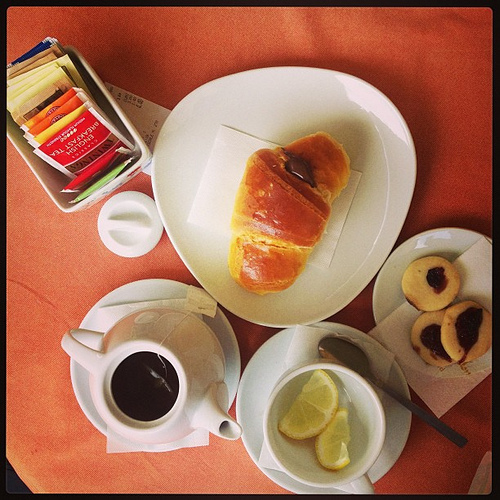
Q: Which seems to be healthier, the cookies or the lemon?
A: The lemon is healthier than the cookies.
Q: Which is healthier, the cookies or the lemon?
A: The lemon is healthier than the cookies.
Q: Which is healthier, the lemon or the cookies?
A: The lemon is healthier than the cookies.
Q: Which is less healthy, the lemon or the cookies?
A: The cookies is less healthy than the lemon.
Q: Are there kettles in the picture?
A: Yes, there is a kettle.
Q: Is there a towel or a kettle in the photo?
A: Yes, there is a kettle.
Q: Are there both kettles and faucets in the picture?
A: No, there is a kettle but no faucets.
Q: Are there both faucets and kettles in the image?
A: No, there is a kettle but no faucets.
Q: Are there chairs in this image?
A: No, there are no chairs.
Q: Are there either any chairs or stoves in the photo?
A: No, there are no chairs or stoves.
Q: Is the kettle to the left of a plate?
A: Yes, the kettle is to the left of a plate.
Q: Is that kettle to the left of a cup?
A: No, the kettle is to the left of a plate.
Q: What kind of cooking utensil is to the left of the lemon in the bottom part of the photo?
A: The cooking utensil is a kettle.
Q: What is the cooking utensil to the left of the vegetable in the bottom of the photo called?
A: The cooking utensil is a kettle.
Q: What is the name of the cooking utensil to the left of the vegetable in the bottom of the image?
A: The cooking utensil is a kettle.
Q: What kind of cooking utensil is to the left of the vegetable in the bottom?
A: The cooking utensil is a kettle.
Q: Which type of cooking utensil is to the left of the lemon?
A: The cooking utensil is a kettle.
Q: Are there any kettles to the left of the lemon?
A: Yes, there is a kettle to the left of the lemon.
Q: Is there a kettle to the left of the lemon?
A: Yes, there is a kettle to the left of the lemon.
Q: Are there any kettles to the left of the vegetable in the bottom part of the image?
A: Yes, there is a kettle to the left of the lemon.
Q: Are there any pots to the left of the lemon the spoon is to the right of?
A: No, there is a kettle to the left of the lemon.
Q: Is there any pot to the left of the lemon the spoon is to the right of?
A: No, there is a kettle to the left of the lemon.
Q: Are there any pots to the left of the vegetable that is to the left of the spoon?
A: No, there is a kettle to the left of the lemon.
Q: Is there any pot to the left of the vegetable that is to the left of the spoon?
A: No, there is a kettle to the left of the lemon.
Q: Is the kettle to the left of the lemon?
A: Yes, the kettle is to the left of the lemon.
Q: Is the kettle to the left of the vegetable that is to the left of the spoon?
A: Yes, the kettle is to the left of the lemon.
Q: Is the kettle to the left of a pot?
A: No, the kettle is to the left of the lemon.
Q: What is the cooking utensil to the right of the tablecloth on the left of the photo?
A: The cooking utensil is a kettle.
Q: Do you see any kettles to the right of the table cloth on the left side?
A: Yes, there is a kettle to the right of the tablecloth.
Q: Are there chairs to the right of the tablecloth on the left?
A: No, there is a kettle to the right of the table cloth.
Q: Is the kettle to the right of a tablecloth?
A: Yes, the kettle is to the right of a tablecloth.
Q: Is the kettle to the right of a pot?
A: No, the kettle is to the right of a tablecloth.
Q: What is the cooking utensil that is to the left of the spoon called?
A: The cooking utensil is a kettle.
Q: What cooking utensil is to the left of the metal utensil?
A: The cooking utensil is a kettle.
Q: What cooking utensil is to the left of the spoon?
A: The cooking utensil is a kettle.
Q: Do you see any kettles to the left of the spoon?
A: Yes, there is a kettle to the left of the spoon.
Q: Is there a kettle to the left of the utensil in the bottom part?
A: Yes, there is a kettle to the left of the spoon.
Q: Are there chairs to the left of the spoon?
A: No, there is a kettle to the left of the spoon.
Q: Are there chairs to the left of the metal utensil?
A: No, there is a kettle to the left of the spoon.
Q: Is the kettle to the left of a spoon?
A: Yes, the kettle is to the left of a spoon.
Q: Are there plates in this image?
A: Yes, there is a plate.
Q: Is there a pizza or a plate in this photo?
A: Yes, there is a plate.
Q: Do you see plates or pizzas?
A: Yes, there is a plate.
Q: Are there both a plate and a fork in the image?
A: No, there is a plate but no forks.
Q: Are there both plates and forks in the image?
A: No, there is a plate but no forks.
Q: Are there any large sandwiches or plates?
A: Yes, there is a large plate.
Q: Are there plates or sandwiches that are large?
A: Yes, the plate is large.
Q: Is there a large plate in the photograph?
A: Yes, there is a large plate.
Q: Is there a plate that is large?
A: Yes, there is a plate that is large.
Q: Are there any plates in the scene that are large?
A: Yes, there is a plate that is large.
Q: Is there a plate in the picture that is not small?
A: Yes, there is a large plate.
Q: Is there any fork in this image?
A: No, there are no forks.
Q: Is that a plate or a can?
A: That is a plate.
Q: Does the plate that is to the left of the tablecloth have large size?
A: Yes, the plate is large.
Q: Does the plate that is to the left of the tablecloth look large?
A: Yes, the plate is large.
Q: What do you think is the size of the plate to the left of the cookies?
A: The plate is large.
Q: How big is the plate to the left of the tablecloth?
A: The plate is large.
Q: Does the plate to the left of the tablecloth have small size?
A: No, the plate is large.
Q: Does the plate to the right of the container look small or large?
A: The plate is large.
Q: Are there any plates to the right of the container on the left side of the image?
A: Yes, there is a plate to the right of the container.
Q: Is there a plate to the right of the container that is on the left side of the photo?
A: Yes, there is a plate to the right of the container.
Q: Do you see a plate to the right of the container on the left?
A: Yes, there is a plate to the right of the container.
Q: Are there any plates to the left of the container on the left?
A: No, the plate is to the right of the container.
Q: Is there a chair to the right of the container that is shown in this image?
A: No, there is a plate to the right of the container.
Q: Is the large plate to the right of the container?
A: Yes, the plate is to the right of the container.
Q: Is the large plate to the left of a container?
A: No, the plate is to the right of a container.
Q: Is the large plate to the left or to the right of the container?
A: The plate is to the right of the container.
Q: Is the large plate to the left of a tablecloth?
A: Yes, the plate is to the left of a tablecloth.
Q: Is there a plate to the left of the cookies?
A: Yes, there is a plate to the left of the cookies.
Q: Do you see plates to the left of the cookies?
A: Yes, there is a plate to the left of the cookies.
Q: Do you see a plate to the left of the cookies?
A: Yes, there is a plate to the left of the cookies.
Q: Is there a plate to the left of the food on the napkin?
A: Yes, there is a plate to the left of the cookies.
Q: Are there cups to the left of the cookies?
A: No, there is a plate to the left of the cookies.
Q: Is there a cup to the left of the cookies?
A: No, there is a plate to the left of the cookies.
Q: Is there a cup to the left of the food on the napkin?
A: No, there is a plate to the left of the cookies.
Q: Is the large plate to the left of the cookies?
A: Yes, the plate is to the left of the cookies.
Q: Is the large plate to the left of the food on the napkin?
A: Yes, the plate is to the left of the cookies.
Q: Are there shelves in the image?
A: No, there are no shelves.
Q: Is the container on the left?
A: Yes, the container is on the left of the image.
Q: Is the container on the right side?
A: No, the container is on the left of the image.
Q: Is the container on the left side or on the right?
A: The container is on the left of the image.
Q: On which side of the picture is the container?
A: The container is on the left of the image.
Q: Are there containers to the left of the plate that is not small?
A: Yes, there is a container to the left of the plate.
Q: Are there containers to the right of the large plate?
A: No, the container is to the left of the plate.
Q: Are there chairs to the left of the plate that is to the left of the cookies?
A: No, there is a container to the left of the plate.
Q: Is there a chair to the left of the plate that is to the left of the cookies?
A: No, there is a container to the left of the plate.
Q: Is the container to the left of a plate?
A: Yes, the container is to the left of a plate.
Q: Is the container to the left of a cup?
A: No, the container is to the left of a plate.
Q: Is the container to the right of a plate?
A: No, the container is to the left of a plate.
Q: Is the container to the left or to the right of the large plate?
A: The container is to the left of the plate.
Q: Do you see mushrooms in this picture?
A: No, there are no mushrooms.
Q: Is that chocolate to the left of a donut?
A: No, the chocolate is to the left of the tablecloth.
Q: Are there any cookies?
A: Yes, there are cookies.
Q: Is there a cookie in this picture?
A: Yes, there are cookies.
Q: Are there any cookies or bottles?
A: Yes, there are cookies.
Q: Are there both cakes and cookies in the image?
A: No, there are cookies but no cakes.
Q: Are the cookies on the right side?
A: Yes, the cookies are on the right of the image.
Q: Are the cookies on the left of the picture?
A: No, the cookies are on the right of the image.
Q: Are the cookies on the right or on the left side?
A: The cookies are on the right of the image.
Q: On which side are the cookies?
A: The cookies are on the right of the image.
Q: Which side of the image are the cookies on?
A: The cookies are on the right of the image.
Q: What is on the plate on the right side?
A: The cookies are on the plate.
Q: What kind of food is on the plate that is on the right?
A: The food is cookies.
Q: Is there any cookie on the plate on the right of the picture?
A: Yes, there are cookies on the plate.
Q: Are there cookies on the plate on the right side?
A: Yes, there are cookies on the plate.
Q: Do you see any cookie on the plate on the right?
A: Yes, there are cookies on the plate.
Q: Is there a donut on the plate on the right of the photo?
A: No, there are cookies on the plate.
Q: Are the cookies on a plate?
A: Yes, the cookies are on a plate.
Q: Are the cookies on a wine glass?
A: No, the cookies are on a plate.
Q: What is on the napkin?
A: The cookies are on the napkin.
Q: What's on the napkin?
A: The cookies are on the napkin.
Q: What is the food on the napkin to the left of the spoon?
A: The food is cookies.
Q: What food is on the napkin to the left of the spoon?
A: The food is cookies.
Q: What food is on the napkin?
A: The food is cookies.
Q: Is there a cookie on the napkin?
A: Yes, there are cookies on the napkin.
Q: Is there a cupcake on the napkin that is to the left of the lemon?
A: No, there are cookies on the napkin.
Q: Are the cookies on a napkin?
A: Yes, the cookies are on a napkin.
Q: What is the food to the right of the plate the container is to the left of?
A: The food is cookies.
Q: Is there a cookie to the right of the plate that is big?
A: Yes, there are cookies to the right of the plate.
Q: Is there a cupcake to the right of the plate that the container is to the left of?
A: No, there are cookies to the right of the plate.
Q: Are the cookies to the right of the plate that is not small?
A: Yes, the cookies are to the right of the plate.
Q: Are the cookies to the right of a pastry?
A: No, the cookies are to the right of the plate.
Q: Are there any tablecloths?
A: Yes, there is a tablecloth.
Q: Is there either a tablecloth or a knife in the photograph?
A: Yes, there is a tablecloth.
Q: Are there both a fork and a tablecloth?
A: No, there is a tablecloth but no forks.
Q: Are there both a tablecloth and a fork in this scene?
A: No, there is a tablecloth but no forks.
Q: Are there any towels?
A: No, there are no towels.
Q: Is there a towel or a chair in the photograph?
A: No, there are no towels or chairs.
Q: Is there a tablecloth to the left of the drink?
A: Yes, there is a tablecloth to the left of the drink.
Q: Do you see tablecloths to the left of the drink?
A: Yes, there is a tablecloth to the left of the drink.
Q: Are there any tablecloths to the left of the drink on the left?
A: Yes, there is a tablecloth to the left of the drink.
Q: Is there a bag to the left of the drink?
A: No, there is a tablecloth to the left of the drink.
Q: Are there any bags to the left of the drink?
A: No, there is a tablecloth to the left of the drink.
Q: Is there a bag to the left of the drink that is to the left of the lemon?
A: No, there is a tablecloth to the left of the drink.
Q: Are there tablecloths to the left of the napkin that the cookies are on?
A: Yes, there is a tablecloth to the left of the napkin.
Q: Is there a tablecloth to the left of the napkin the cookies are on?
A: Yes, there is a tablecloth to the left of the napkin.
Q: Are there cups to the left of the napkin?
A: No, there is a tablecloth to the left of the napkin.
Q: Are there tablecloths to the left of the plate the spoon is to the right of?
A: Yes, there is a tablecloth to the left of the plate.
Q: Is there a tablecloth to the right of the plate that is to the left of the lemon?
A: No, the tablecloth is to the left of the plate.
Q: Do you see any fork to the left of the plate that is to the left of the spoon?
A: No, there is a tablecloth to the left of the plate.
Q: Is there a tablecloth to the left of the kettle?
A: Yes, there is a tablecloth to the left of the kettle.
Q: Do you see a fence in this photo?
A: No, there are no fences.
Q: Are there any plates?
A: Yes, there is a plate.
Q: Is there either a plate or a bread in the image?
A: Yes, there is a plate.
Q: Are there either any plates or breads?
A: Yes, there is a plate.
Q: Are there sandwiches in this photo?
A: No, there are no sandwiches.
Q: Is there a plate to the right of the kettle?
A: Yes, there is a plate to the right of the kettle.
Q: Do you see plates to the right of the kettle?
A: Yes, there is a plate to the right of the kettle.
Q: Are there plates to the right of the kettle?
A: Yes, there is a plate to the right of the kettle.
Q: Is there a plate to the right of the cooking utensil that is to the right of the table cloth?
A: Yes, there is a plate to the right of the kettle.